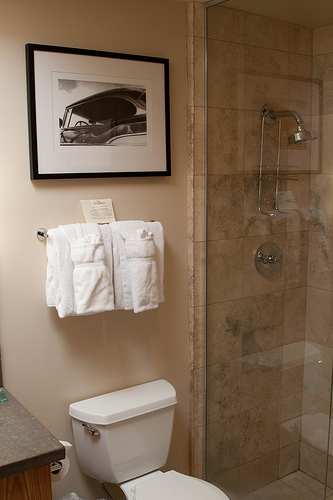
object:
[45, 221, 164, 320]
towels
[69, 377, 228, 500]
toilet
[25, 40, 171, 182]
picture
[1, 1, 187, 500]
wall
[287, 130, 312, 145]
showerhead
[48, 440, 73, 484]
toilet paper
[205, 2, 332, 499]
door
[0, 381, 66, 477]
counter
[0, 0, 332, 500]
bathroom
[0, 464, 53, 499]
cabinet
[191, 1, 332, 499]
shower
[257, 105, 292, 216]
caddy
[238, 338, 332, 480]
reflection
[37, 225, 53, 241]
towel rack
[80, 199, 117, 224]
note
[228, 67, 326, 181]
reflection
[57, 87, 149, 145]
car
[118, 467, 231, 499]
toilet seat cover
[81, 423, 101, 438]
flush handle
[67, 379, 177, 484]
toilet tank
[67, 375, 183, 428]
cover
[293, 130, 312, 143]
rounded head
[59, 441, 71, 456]
toilet roll holder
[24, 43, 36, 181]
black frame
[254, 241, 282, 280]
shower tap